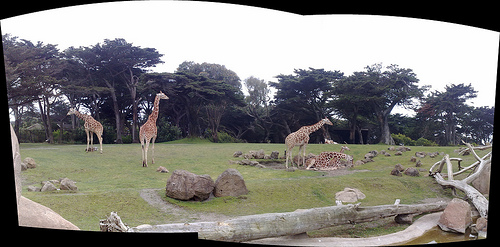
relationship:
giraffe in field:
[134, 92, 164, 167] [251, 168, 307, 191]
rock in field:
[172, 167, 224, 194] [45, 64, 435, 218]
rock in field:
[152, 162, 172, 177] [17, 143, 492, 243]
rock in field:
[21, 153, 36, 169] [15, 33, 486, 227]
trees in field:
[3, 30, 494, 148] [17, 143, 492, 243]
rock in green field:
[165, 169, 216, 200] [20, 142, 485, 239]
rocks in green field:
[25, 176, 77, 193] [20, 142, 485, 239]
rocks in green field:
[357, 145, 440, 166] [20, 142, 485, 239]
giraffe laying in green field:
[304, 146, 350, 171] [20, 142, 496, 229]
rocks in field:
[25, 176, 77, 193] [17, 143, 492, 243]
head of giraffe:
[62, 105, 77, 117] [67, 106, 106, 153]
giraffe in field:
[67, 106, 106, 153] [17, 143, 492, 243]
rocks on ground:
[357, 141, 440, 178] [7, 140, 497, 239]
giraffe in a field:
[67, 106, 106, 153] [17, 143, 492, 243]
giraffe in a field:
[301, 150, 361, 168] [17, 143, 492, 243]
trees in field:
[3, 30, 494, 148] [2, 139, 499, 201]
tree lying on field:
[169, 74, 301, 138] [17, 143, 492, 243]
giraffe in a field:
[277, 109, 339, 171] [16, 133, 476, 238]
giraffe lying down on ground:
[297, 144, 361, 170] [7, 140, 497, 239]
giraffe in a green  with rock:
[67, 104, 105, 151] [240, 147, 268, 164]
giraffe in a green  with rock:
[67, 104, 105, 151] [389, 161, 404, 178]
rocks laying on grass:
[357, 145, 440, 166] [20, 140, 483, 240]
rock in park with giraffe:
[165, 169, 216, 200] [136, 89, 161, 164]